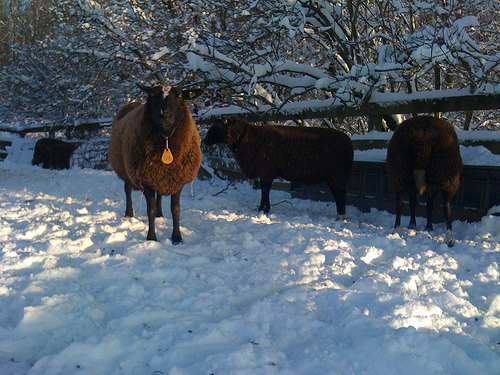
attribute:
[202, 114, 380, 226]
sheep — black, brown, white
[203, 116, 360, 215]
sheep — black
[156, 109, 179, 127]
nose — black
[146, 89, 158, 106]
eye — open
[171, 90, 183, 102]
eye — open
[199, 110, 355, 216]
sheep — brown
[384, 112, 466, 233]
sheep — brown, black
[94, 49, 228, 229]
sheep — brown, black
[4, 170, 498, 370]
snow — white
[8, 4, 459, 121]
tree — leafless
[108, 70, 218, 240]
board — black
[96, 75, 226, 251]
sheep — brown, black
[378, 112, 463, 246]
sheep — black, brown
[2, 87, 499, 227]
fence — wooden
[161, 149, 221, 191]
tag — yellow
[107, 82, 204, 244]
sheep — brown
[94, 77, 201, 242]
sheep — brown, black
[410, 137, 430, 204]
tail — drooping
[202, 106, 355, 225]
sheep — black, brown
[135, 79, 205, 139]
head — black